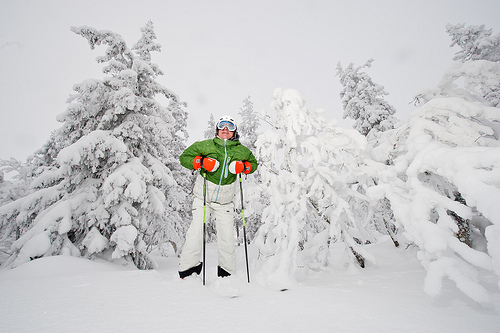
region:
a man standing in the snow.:
[141, 90, 303, 297]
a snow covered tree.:
[0, 17, 197, 328]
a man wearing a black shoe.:
[207, 259, 239, 285]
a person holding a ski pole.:
[226, 159, 274, 293]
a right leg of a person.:
[158, 194, 218, 289]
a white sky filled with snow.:
[0, 0, 499, 159]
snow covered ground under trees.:
[0, 251, 497, 326]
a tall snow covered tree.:
[324, 51, 413, 153]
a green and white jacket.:
[181, 122, 275, 205]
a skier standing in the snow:
[179, 107, 274, 307]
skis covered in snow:
[141, 280, 283, 300]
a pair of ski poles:
[196, 170, 274, 282]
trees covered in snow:
[44, 35, 483, 257]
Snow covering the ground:
[8, 241, 495, 330]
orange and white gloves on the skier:
[196, 150, 252, 182]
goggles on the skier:
[214, 116, 239, 132]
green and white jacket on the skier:
[185, 135, 257, 202]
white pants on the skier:
[180, 200, 257, 284]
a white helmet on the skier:
[210, 105, 244, 132]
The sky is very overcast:
[1, 2, 496, 101]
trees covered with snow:
[31, 17, 176, 272]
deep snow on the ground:
[6, 242, 170, 332]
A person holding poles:
[148, 90, 288, 299]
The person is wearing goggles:
[162, 88, 269, 303]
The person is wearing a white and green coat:
[166, 95, 290, 307]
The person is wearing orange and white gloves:
[160, 97, 267, 297]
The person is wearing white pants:
[157, 93, 267, 303]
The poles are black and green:
[187, 148, 263, 291]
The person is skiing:
[151, 98, 318, 318]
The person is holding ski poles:
[167, 107, 282, 299]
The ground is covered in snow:
[11, 248, 498, 325]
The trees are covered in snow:
[5, 18, 499, 301]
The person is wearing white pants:
[164, 187, 270, 295]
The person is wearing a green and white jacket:
[181, 132, 253, 200]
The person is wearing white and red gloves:
[193, 154, 260, 176]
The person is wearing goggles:
[216, 118, 239, 130]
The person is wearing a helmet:
[213, 116, 243, 124]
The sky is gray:
[8, 5, 496, 141]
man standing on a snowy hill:
[172, 101, 266, 288]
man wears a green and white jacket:
[166, 107, 268, 293]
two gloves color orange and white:
[190, 151, 252, 182]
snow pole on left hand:
[225, 157, 262, 287]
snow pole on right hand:
[192, 151, 221, 289]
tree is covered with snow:
[0, 21, 182, 266]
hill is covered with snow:
[15, 250, 486, 326]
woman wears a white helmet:
[200, 113, 251, 153]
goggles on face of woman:
[212, 118, 239, 133]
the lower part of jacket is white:
[173, 137, 260, 205]